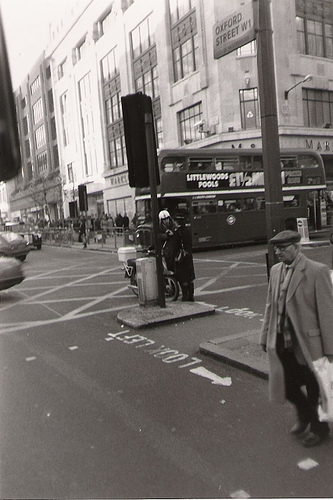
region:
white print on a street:
[105, 326, 234, 391]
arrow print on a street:
[189, 365, 235, 386]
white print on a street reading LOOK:
[142, 344, 203, 369]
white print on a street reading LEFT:
[104, 326, 155, 350]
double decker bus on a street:
[157, 147, 332, 251]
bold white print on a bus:
[185, 171, 229, 189]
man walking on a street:
[257, 227, 332, 447]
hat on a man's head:
[265, 229, 302, 246]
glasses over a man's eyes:
[270, 241, 294, 251]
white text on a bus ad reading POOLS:
[197, 180, 220, 186]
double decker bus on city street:
[132, 141, 327, 247]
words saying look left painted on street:
[103, 327, 234, 386]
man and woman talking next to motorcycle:
[155, 207, 194, 303]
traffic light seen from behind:
[119, 89, 162, 191]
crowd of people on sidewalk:
[8, 208, 131, 248]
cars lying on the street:
[0, 216, 42, 297]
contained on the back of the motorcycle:
[116, 243, 141, 262]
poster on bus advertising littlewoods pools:
[186, 171, 229, 189]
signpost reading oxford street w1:
[210, 0, 260, 60]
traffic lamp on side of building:
[282, 72, 314, 102]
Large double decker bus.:
[132, 146, 326, 247]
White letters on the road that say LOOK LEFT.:
[107, 325, 201, 368]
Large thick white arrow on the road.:
[189, 365, 232, 387]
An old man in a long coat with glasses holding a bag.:
[259, 230, 332, 446]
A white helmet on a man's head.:
[159, 208, 169, 217]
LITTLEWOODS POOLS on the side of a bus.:
[186, 172, 229, 187]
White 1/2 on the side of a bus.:
[239, 171, 251, 185]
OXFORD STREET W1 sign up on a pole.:
[210, 4, 258, 60]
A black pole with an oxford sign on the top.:
[255, 1, 286, 284]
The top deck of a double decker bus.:
[134, 148, 326, 194]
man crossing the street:
[256, 233, 326, 471]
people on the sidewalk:
[79, 212, 135, 227]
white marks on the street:
[104, 328, 239, 391]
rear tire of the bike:
[161, 274, 183, 303]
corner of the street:
[106, 230, 150, 252]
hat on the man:
[264, 224, 304, 241]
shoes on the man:
[283, 413, 319, 454]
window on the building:
[172, 44, 199, 68]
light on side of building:
[286, 71, 314, 100]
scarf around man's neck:
[269, 263, 305, 362]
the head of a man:
[259, 203, 304, 291]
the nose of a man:
[267, 239, 285, 263]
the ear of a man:
[292, 233, 310, 261]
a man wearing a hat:
[266, 212, 314, 273]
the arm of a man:
[311, 248, 331, 362]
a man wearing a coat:
[244, 230, 321, 386]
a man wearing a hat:
[254, 212, 302, 256]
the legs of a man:
[281, 342, 330, 449]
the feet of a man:
[257, 409, 329, 464]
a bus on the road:
[102, 110, 298, 283]